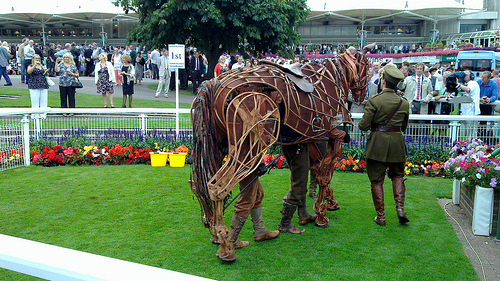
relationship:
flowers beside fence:
[2, 129, 500, 191] [1, 105, 499, 177]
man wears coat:
[403, 62, 434, 116] [402, 75, 433, 114]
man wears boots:
[276, 125, 321, 236] [278, 197, 317, 236]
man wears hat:
[357, 63, 410, 227] [383, 63, 405, 87]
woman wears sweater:
[93, 51, 119, 107] [93, 60, 116, 84]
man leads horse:
[357, 63, 410, 227] [187, 46, 373, 264]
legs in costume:
[228, 132, 317, 250] [187, 46, 373, 264]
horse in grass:
[187, 46, 373, 264] [0, 83, 477, 280]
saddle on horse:
[257, 58, 326, 133] [187, 46, 373, 264]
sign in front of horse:
[165, 43, 186, 72] [187, 46, 373, 264]